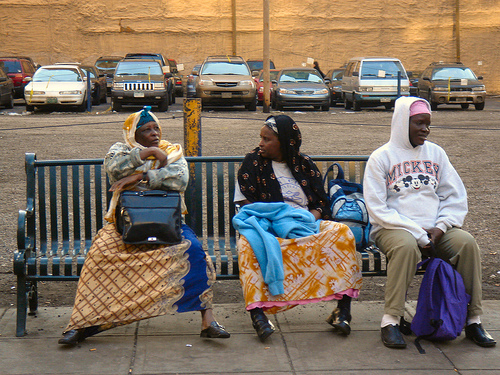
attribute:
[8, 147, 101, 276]
bench — blue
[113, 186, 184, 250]
bag — black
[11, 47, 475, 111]
cars — parked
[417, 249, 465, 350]
backpack — purple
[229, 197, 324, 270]
sweater — blue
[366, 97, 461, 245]
hoodie — white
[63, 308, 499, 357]
shoes — black